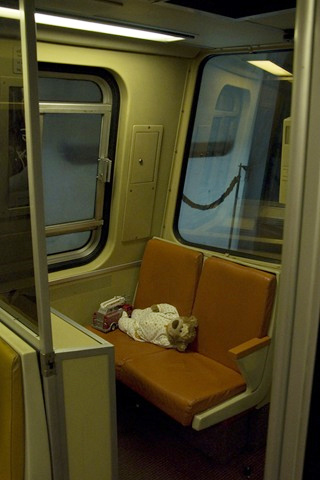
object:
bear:
[121, 301, 200, 356]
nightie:
[119, 304, 179, 347]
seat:
[81, 233, 273, 426]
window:
[9, 69, 101, 259]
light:
[1, 8, 187, 43]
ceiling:
[1, 2, 296, 61]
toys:
[90, 294, 132, 337]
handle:
[98, 154, 112, 184]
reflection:
[207, 75, 256, 161]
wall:
[4, 38, 196, 329]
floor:
[121, 388, 267, 479]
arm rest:
[227, 335, 279, 389]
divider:
[2, 0, 51, 354]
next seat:
[1, 318, 56, 479]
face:
[172, 317, 190, 343]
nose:
[172, 319, 181, 334]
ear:
[186, 313, 202, 331]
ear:
[173, 344, 190, 355]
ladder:
[102, 293, 127, 313]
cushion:
[90, 320, 247, 424]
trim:
[2, 3, 119, 479]